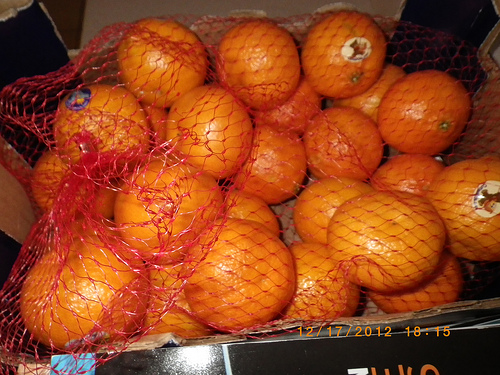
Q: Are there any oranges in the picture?
A: Yes, there are oranges.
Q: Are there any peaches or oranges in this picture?
A: Yes, there are oranges.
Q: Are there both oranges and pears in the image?
A: No, there are oranges but no pears.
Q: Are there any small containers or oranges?
A: Yes, there are small oranges.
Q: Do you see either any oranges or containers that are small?
A: Yes, the oranges are small.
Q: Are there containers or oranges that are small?
A: Yes, the oranges are small.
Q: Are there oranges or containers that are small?
A: Yes, the oranges are small.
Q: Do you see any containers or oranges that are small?
A: Yes, the oranges are small.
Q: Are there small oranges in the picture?
A: Yes, there are small oranges.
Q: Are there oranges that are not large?
A: Yes, there are small oranges.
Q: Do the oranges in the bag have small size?
A: Yes, the oranges are small.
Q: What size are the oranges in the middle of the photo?
A: The oranges are small.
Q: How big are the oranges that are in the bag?
A: The oranges are small.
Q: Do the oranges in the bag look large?
A: No, the oranges are small.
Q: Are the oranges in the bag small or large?
A: The oranges are small.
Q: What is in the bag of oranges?
A: The oranges are in the bag.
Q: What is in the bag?
A: The oranges are in the bag.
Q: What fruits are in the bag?
A: The fruits are oranges.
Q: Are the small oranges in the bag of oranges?
A: Yes, the oranges are in the bag.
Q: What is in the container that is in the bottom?
A: The oranges are in the box.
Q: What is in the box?
A: The oranges are in the box.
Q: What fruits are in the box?
A: The fruits are oranges.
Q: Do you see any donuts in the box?
A: No, there are oranges in the box.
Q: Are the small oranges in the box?
A: Yes, the oranges are in the box.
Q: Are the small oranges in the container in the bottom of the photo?
A: Yes, the oranges are in the box.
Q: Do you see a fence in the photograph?
A: No, there are no fences.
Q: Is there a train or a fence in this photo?
A: No, there are no fences or trains.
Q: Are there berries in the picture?
A: No, there are no berries.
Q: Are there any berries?
A: No, there are no berries.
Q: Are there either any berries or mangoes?
A: No, there are no berries or mangoes.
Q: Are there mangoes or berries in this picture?
A: No, there are no berries or mangoes.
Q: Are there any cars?
A: No, there are no cars.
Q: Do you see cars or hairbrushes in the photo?
A: No, there are no cars or hairbrushes.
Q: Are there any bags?
A: Yes, there is a bag.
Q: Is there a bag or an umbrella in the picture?
A: Yes, there is a bag.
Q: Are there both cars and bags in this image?
A: No, there is a bag but no cars.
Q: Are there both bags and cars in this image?
A: No, there is a bag but no cars.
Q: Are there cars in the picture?
A: No, there are no cars.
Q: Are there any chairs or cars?
A: No, there are no cars or chairs.